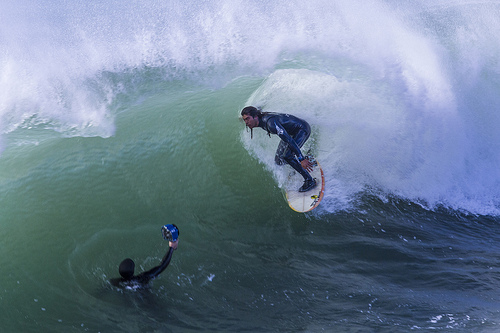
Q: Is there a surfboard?
A: Yes, there is a surfboard.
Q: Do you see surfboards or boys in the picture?
A: Yes, there is a surfboard.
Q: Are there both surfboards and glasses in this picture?
A: No, there is a surfboard but no glasses.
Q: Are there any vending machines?
A: No, there are no vending machines.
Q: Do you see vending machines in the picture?
A: No, there are no vending machines.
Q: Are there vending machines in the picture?
A: No, there are no vending machines.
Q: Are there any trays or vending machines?
A: No, there are no vending machines or trays.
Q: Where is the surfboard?
A: The surfboard is in the water.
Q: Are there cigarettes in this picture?
A: No, there are no cigarettes.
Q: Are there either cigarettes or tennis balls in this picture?
A: No, there are no cigarettes or tennis balls.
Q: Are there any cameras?
A: Yes, there is a camera.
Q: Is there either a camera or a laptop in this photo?
A: Yes, there is a camera.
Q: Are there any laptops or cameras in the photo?
A: Yes, there is a camera.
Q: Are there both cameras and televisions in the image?
A: No, there is a camera but no televisions.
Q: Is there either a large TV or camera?
A: Yes, there is a large camera.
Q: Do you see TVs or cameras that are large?
A: Yes, the camera is large.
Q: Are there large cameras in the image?
A: Yes, there is a large camera.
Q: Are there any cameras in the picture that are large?
A: Yes, there is a camera that is large.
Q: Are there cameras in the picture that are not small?
A: Yes, there is a large camera.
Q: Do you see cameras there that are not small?
A: Yes, there is a large camera.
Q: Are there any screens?
A: No, there are no screens.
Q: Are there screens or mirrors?
A: No, there are no screens or mirrors.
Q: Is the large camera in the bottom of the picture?
A: Yes, the camera is in the bottom of the image.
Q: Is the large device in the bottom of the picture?
A: Yes, the camera is in the bottom of the image.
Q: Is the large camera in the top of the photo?
A: No, the camera is in the bottom of the image.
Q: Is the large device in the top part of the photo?
A: No, the camera is in the bottom of the image.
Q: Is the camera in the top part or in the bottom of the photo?
A: The camera is in the bottom of the image.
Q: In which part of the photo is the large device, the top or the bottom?
A: The camera is in the bottom of the image.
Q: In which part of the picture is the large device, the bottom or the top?
A: The camera is in the bottom of the image.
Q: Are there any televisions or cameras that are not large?
A: No, there is a camera but it is large.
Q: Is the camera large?
A: Yes, the camera is large.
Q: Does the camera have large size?
A: Yes, the camera is large.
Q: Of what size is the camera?
A: The camera is large.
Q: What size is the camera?
A: The camera is large.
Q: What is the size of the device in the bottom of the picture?
A: The camera is large.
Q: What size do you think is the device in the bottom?
A: The camera is large.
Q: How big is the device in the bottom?
A: The camera is large.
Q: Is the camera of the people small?
A: No, the camera is large.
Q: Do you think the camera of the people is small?
A: No, the camera is large.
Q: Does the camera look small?
A: No, the camera is large.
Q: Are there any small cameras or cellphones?
A: No, there is a camera but it is large.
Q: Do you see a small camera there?
A: No, there is a camera but it is large.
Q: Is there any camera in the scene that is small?
A: No, there is a camera but it is large.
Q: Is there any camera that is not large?
A: No, there is a camera but it is large.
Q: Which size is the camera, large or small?
A: The camera is large.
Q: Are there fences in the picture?
A: No, there are no fences.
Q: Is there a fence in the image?
A: No, there are no fences.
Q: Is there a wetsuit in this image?
A: Yes, there is a wetsuit.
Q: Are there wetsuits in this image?
A: Yes, there is a wetsuit.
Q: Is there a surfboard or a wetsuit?
A: Yes, there is a wetsuit.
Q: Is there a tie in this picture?
A: No, there are no ties.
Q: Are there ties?
A: No, there are no ties.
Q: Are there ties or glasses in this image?
A: No, there are no ties or glasses.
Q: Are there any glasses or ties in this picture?
A: No, there are no ties or glasses.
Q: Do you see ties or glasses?
A: No, there are no ties or glasses.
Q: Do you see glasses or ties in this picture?
A: No, there are no ties or glasses.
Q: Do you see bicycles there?
A: No, there are no bicycles.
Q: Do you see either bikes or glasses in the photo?
A: No, there are no bikes or glasses.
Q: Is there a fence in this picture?
A: No, there are no fences.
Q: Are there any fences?
A: No, there are no fences.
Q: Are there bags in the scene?
A: No, there are no bags.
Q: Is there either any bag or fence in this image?
A: No, there are no bags or fences.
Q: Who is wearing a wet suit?
A: The people are wearing a wet suit.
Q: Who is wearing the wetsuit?
A: The people are wearing a wet suit.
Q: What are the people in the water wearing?
A: The people are wearing a wetsuit.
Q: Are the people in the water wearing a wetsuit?
A: Yes, the people are wearing a wetsuit.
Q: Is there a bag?
A: No, there are no bags.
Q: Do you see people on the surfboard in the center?
A: Yes, there is a person on the surfboard.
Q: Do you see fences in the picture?
A: No, there are no fences.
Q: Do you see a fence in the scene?
A: No, there are no fences.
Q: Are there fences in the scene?
A: No, there are no fences.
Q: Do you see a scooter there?
A: No, there are no scooters.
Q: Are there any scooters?
A: No, there are no scooters.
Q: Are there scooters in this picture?
A: No, there are no scooters.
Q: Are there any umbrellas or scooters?
A: No, there are no scooters or umbrellas.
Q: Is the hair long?
A: Yes, the hair is long.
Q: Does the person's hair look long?
A: Yes, the hair is long.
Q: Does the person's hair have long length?
A: Yes, the hair is long.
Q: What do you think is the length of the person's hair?
A: The hair is long.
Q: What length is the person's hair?
A: The hair is long.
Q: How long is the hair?
A: The hair is long.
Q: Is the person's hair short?
A: No, the hair is long.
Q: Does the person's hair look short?
A: No, the hair is long.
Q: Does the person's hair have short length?
A: No, the hair is long.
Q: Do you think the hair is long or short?
A: The hair is long.